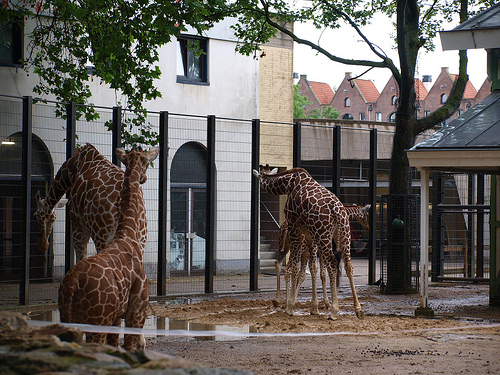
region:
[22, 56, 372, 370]
four giraffes in an enclosure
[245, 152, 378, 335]
two giraffes are standing in mud on right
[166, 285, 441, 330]
large muddy area close to the fence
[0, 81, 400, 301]
a black fence enclosing the animals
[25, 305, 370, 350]
a large puddle of water by the fence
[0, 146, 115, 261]
giraffe on left is bending down neck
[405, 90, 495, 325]
a structure with a roof inside of the enclosure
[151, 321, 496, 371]
dirt terrain in the enclosure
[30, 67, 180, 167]
tree branches leaning over the tree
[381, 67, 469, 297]
a large tree inside of enclosure on the right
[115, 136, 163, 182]
the head of a giraffe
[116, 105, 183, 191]
the head of a giraffe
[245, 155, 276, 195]
the head of a giraffe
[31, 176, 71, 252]
the head of a giraffe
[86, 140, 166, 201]
the head of a giraffe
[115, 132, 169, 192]
head of a giraffe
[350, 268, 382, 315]
leg of a giraffe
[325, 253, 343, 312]
leg of a giraffe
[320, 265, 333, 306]
leg of a giraffe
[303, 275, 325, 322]
leg of a giraffe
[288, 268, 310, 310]
leg of a giraffe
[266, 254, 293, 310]
leg of a giraffe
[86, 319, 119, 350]
leg of a giraffe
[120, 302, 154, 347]
leg of a giraffe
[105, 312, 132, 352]
leg of a giraffe